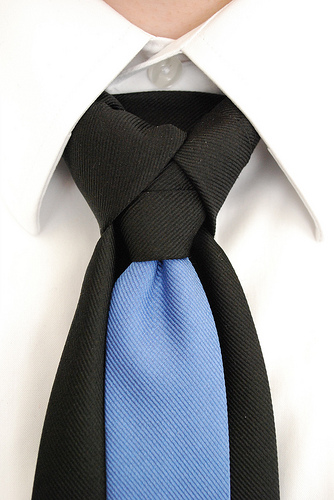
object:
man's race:
[107, 0, 224, 54]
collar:
[3, 1, 333, 246]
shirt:
[0, 0, 334, 499]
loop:
[59, 82, 271, 260]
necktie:
[23, 84, 307, 500]